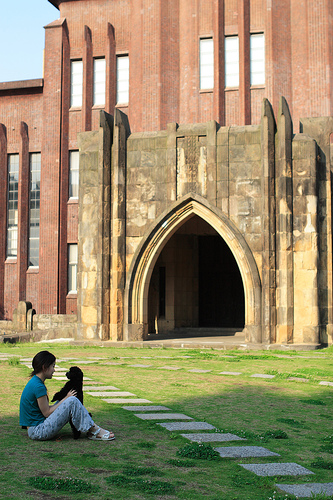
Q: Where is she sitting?
A: On the grass.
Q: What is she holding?
A: A puppy.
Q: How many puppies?
A: One.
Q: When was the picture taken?
A: Daytime.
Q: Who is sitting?
A: Lady.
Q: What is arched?
A: Doorway.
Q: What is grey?
A: Sidewalk.